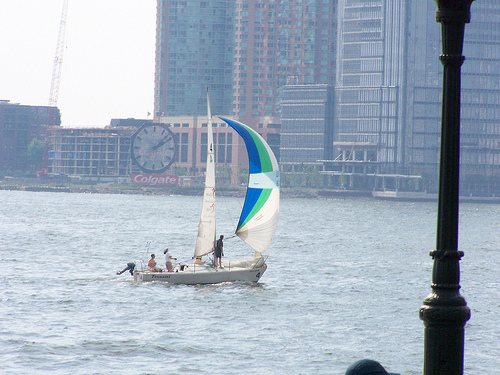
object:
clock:
[129, 122, 178, 174]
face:
[133, 125, 176, 170]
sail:
[214, 114, 280, 253]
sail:
[194, 85, 216, 266]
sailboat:
[115, 85, 281, 284]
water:
[0, 187, 500, 372]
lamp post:
[419, 0, 471, 375]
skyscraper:
[336, 0, 497, 171]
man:
[212, 234, 224, 268]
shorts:
[214, 251, 221, 258]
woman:
[163, 247, 177, 272]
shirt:
[164, 253, 174, 262]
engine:
[116, 260, 136, 276]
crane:
[47, 3, 71, 111]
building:
[0, 100, 62, 177]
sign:
[133, 175, 176, 186]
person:
[147, 254, 162, 273]